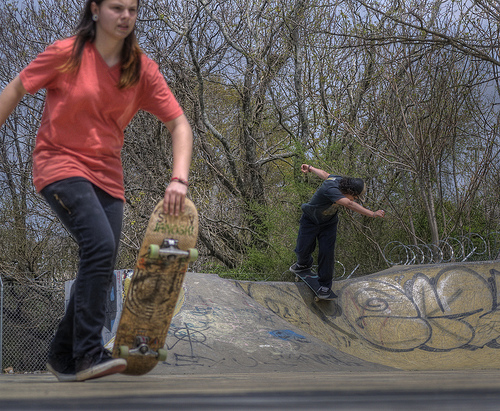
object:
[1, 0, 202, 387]
girl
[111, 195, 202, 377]
skateboard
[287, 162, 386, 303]
man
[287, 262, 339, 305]
skateboard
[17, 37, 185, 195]
shirt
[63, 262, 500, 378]
wall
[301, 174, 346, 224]
shirt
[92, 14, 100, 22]
earring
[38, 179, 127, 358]
pants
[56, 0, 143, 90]
hair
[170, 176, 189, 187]
bracelet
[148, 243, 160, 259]
wheel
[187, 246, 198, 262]
wheel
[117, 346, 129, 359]
wheel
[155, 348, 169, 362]
wheel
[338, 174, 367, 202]
hat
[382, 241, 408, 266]
wire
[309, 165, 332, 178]
arm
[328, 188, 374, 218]
arm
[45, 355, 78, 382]
shoe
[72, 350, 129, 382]
shoe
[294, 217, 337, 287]
jeans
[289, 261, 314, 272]
shoe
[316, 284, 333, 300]
shoe